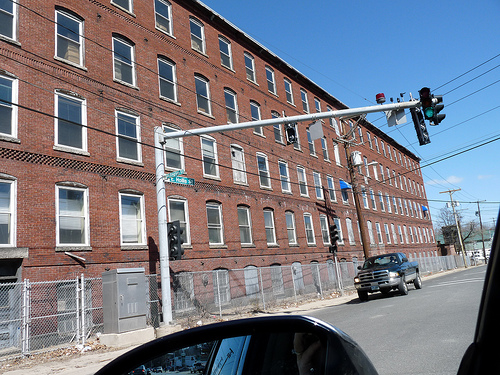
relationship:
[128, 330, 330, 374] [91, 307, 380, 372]
reflection in mirror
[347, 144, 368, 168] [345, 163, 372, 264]
transformer on pole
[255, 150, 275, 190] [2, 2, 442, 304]
window on building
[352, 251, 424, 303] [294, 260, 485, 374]
truck parked on street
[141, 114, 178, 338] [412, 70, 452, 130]
metal pole holding light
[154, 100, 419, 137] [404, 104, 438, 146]
bar holding lights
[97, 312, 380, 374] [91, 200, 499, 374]
mirror on a car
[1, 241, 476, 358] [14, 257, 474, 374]
fence on a sidewalk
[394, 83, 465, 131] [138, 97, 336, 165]
light on a pole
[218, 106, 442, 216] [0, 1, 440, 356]
window on a building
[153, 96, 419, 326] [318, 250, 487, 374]
pole on side of street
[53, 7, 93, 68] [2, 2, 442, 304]
window on building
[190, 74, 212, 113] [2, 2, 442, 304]
window on building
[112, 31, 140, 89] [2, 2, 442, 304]
window on building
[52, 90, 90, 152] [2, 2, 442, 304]
window on building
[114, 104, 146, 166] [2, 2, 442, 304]
window on building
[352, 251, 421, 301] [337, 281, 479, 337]
truck on ground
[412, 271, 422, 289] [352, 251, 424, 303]
wheel of truck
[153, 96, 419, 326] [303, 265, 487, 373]
pole above street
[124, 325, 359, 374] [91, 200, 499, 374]
mirror of car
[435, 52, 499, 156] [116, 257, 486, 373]
wires above street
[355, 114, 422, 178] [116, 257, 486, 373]
wires above street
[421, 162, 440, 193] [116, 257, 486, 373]
wires above street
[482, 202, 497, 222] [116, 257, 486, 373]
wires above street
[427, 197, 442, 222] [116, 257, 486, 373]
wires above street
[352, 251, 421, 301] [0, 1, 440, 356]
truck near building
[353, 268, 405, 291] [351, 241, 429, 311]
headlights on truck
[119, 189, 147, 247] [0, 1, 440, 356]
window to building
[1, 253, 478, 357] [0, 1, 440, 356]
fence barricades building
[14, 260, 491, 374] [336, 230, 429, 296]
sidewalk under truck